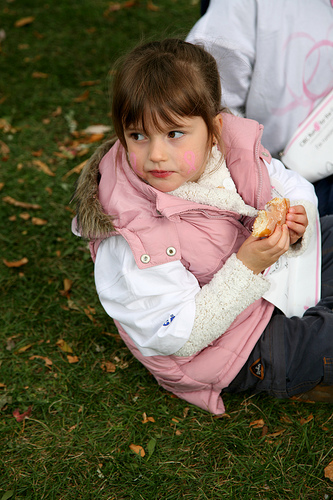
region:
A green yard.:
[1, 0, 331, 497]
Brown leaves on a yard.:
[4, 329, 121, 382]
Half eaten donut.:
[252, 194, 294, 242]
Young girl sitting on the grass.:
[65, 34, 331, 420]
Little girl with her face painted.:
[105, 33, 222, 193]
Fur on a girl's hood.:
[69, 136, 123, 233]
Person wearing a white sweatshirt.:
[188, 0, 331, 151]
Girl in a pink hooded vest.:
[79, 36, 302, 416]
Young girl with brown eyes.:
[107, 32, 227, 196]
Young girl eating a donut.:
[78, 35, 330, 403]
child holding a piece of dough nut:
[245, 193, 310, 261]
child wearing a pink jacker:
[100, 193, 247, 381]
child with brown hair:
[99, 32, 216, 149]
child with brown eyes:
[123, 126, 184, 143]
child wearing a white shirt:
[109, 237, 207, 345]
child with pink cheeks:
[172, 150, 205, 174]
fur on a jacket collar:
[75, 163, 101, 235]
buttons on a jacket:
[136, 246, 177, 264]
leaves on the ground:
[115, 406, 164, 461]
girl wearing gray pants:
[254, 311, 332, 374]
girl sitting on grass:
[77, 38, 326, 413]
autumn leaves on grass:
[2, 9, 329, 497]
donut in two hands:
[245, 198, 308, 261]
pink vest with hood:
[80, 115, 274, 410]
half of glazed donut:
[254, 199, 288, 238]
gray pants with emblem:
[241, 301, 329, 395]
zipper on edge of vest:
[252, 125, 266, 206]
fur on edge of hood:
[74, 139, 117, 233]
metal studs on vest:
[138, 246, 177, 264]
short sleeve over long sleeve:
[95, 247, 266, 355]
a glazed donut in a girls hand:
[251, 193, 291, 238]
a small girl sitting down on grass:
[75, 27, 324, 405]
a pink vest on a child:
[52, 108, 304, 428]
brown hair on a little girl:
[99, 41, 230, 160]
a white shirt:
[83, 159, 315, 363]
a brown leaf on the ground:
[127, 437, 146, 461]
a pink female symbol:
[269, 25, 329, 124]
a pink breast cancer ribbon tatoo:
[181, 146, 197, 172]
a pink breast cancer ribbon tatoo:
[123, 147, 147, 174]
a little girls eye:
[164, 124, 185, 141]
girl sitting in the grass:
[59, 41, 302, 381]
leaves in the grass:
[103, 400, 219, 483]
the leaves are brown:
[104, 407, 186, 477]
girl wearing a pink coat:
[92, 167, 278, 370]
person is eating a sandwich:
[231, 162, 316, 277]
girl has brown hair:
[84, 24, 225, 154]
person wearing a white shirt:
[94, 250, 203, 362]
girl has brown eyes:
[113, 125, 159, 162]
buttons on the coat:
[123, 231, 189, 267]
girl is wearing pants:
[247, 290, 331, 375]